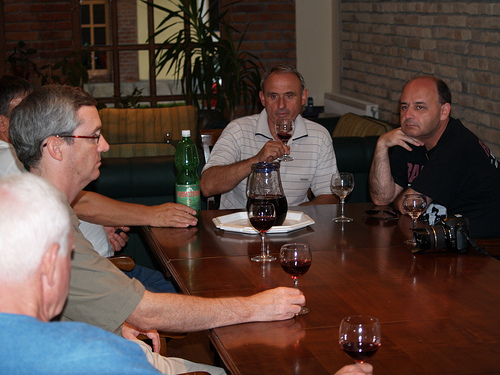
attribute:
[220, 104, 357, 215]
shirt — striped, white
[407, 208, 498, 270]
camera — black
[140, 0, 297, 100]
plant — green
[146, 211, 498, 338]
table — brown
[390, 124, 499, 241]
shirt — black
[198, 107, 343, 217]
shirt — striped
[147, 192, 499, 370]
table — dark brown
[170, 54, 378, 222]
person — drinking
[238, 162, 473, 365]
multiple glasses — wine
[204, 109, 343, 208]
shirt — white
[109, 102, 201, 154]
couch — striped, yellow, green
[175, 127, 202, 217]
bottle — green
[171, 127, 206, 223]
bottle — plastic, green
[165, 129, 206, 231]
bottle — green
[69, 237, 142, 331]
shirt — tan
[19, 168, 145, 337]
shirt — gray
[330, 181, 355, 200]
wine — white